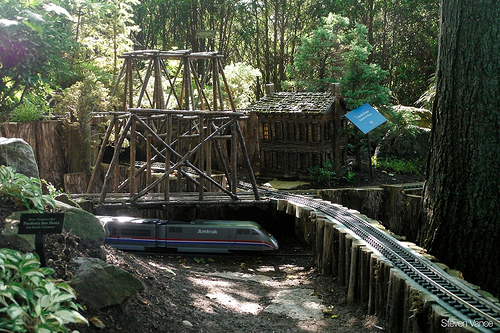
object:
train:
[95, 215, 279, 254]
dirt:
[212, 254, 304, 330]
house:
[251, 82, 348, 180]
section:
[166, 219, 279, 253]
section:
[94, 215, 157, 251]